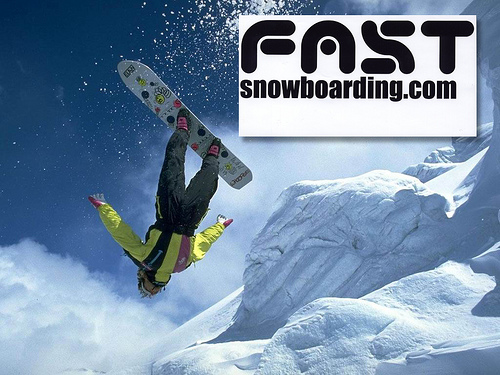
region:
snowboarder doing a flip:
[80, 52, 256, 324]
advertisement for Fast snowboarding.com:
[238, 15, 477, 136]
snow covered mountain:
[142, 133, 499, 374]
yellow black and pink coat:
[97, 200, 221, 282]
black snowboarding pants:
[152, 128, 218, 238]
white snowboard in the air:
[111, 55, 253, 195]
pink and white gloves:
[81, 187, 236, 227]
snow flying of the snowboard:
[42, 0, 327, 137]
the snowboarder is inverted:
[85, 50, 253, 306]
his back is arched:
[80, 50, 243, 304]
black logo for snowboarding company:
[234, 12, 485, 147]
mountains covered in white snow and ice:
[247, 242, 407, 364]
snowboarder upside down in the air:
[82, 46, 263, 318]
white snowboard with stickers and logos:
[113, 56, 259, 195]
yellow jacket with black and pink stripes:
[80, 187, 230, 313]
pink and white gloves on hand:
[88, 188, 111, 214]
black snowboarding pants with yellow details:
[149, 128, 229, 245]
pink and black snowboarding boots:
[172, 105, 224, 162]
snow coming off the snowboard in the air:
[151, 3, 255, 97]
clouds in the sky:
[18, 185, 98, 345]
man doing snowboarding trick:
[61, 64, 216, 297]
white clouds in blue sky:
[9, 16, 68, 80]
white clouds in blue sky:
[9, 64, 54, 139]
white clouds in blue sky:
[22, 145, 76, 195]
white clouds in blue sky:
[6, 172, 70, 226]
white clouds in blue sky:
[46, 19, 105, 78]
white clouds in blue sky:
[54, 104, 128, 146]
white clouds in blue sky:
[30, 134, 130, 171]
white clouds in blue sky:
[146, 8, 207, 52]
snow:
[279, 236, 373, 310]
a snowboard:
[106, 44, 278, 230]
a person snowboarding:
[65, 61, 247, 313]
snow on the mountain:
[261, 170, 498, 366]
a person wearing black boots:
[85, 65, 261, 332]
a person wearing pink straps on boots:
[93, 85, 258, 300]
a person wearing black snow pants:
[87, 80, 239, 333]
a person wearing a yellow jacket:
[68, 95, 260, 342]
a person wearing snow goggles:
[88, 102, 239, 310]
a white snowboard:
[110, 59, 293, 226]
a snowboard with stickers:
[108, 64, 294, 227]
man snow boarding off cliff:
[140, 45, 241, 268]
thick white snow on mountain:
[244, 169, 455, 353]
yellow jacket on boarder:
[143, 231, 223, 293]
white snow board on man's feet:
[137, 56, 283, 186]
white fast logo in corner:
[224, 23, 497, 181]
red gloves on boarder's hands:
[77, 179, 131, 230]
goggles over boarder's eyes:
[112, 271, 161, 298]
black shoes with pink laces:
[176, 105, 195, 129]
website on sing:
[244, 75, 476, 120]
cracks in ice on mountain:
[211, 215, 451, 339]